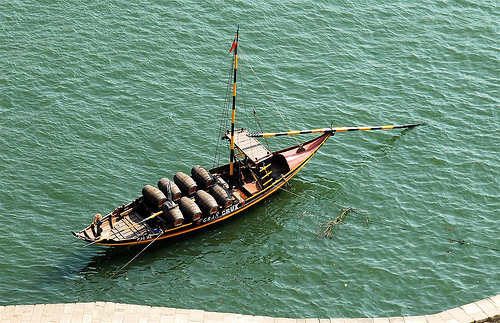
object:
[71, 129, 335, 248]
sailboat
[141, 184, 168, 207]
barrel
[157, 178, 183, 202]
barrel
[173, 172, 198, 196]
barrel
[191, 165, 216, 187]
barrel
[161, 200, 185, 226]
barrel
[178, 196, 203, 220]
barrel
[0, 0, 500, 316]
water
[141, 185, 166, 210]
items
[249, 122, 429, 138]
poles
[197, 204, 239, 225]
writing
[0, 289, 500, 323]
wall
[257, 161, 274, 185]
ladder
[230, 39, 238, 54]
flag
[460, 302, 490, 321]
bricks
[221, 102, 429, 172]
sail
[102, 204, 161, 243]
platform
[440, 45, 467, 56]
waves